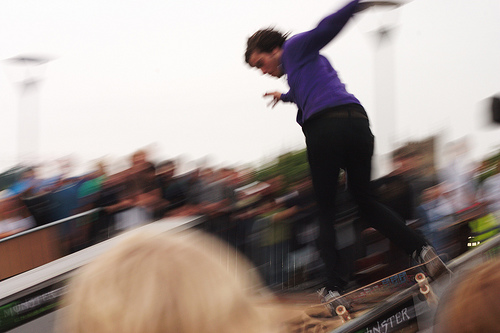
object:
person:
[51, 226, 287, 333]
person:
[103, 150, 160, 210]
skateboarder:
[241, 1, 431, 297]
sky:
[0, 0, 499, 174]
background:
[1, 149, 308, 234]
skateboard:
[306, 253, 455, 321]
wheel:
[335, 303, 347, 317]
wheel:
[415, 270, 428, 282]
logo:
[357, 306, 411, 332]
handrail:
[1, 214, 206, 307]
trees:
[254, 149, 308, 182]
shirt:
[281, 0, 359, 129]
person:
[9, 165, 61, 191]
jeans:
[303, 103, 424, 291]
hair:
[245, 28, 288, 60]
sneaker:
[315, 286, 350, 316]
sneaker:
[414, 243, 452, 283]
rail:
[325, 233, 497, 331]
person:
[195, 165, 242, 186]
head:
[436, 258, 499, 332]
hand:
[261, 90, 281, 108]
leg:
[345, 124, 428, 255]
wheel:
[419, 284, 430, 295]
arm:
[285, 0, 382, 52]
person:
[155, 159, 181, 179]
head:
[242, 26, 289, 79]